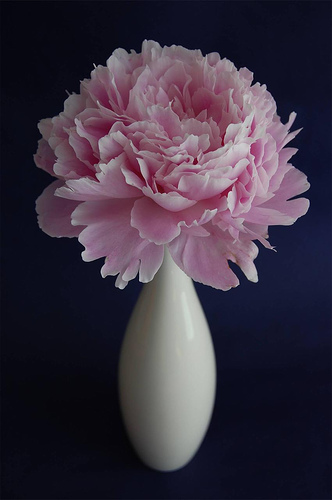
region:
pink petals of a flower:
[59, 43, 288, 259]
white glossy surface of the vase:
[153, 329, 199, 447]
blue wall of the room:
[248, 299, 317, 413]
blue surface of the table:
[228, 425, 315, 486]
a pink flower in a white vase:
[45, 40, 275, 462]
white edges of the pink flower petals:
[244, 252, 270, 289]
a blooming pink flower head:
[25, 32, 307, 288]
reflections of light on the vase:
[131, 287, 202, 348]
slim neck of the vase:
[123, 229, 221, 313]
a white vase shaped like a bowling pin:
[92, 246, 237, 471]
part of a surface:
[263, 445, 272, 456]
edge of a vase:
[154, 443, 161, 458]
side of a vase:
[190, 397, 194, 403]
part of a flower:
[213, 271, 228, 290]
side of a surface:
[252, 384, 261, 404]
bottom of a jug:
[168, 467, 183, 476]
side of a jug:
[142, 430, 150, 447]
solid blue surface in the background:
[228, 304, 312, 334]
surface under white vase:
[134, 464, 206, 481]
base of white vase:
[139, 459, 191, 474]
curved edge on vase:
[195, 424, 212, 449]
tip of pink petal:
[216, 286, 231, 292]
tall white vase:
[115, 265, 240, 470]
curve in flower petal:
[71, 239, 90, 253]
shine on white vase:
[164, 298, 210, 337]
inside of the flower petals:
[151, 117, 211, 174]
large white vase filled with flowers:
[53, 86, 296, 469]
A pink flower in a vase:
[101, 78, 244, 241]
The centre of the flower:
[164, 130, 171, 135]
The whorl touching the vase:
[175, 255, 183, 262]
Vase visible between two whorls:
[164, 248, 167, 253]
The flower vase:
[145, 311, 187, 445]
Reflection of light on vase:
[184, 302, 189, 324]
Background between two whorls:
[233, 266, 237, 271]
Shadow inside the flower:
[198, 97, 203, 105]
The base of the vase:
[158, 466, 175, 469]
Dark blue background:
[256, 292, 303, 320]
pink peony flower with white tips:
[34, 11, 309, 290]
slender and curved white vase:
[118, 242, 211, 469]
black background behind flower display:
[4, 1, 313, 484]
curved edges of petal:
[75, 205, 159, 285]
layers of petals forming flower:
[114, 84, 252, 279]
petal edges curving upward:
[53, 149, 139, 202]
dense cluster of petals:
[141, 79, 230, 133]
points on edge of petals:
[60, 58, 94, 92]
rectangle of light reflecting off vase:
[174, 285, 194, 337]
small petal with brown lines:
[224, 231, 258, 283]